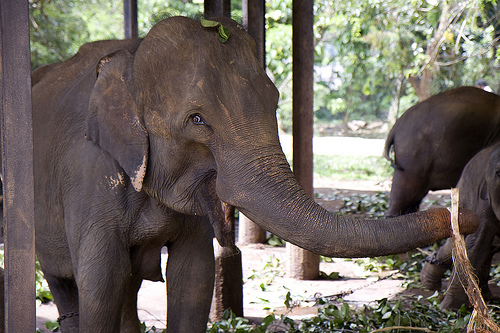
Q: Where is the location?
A: Zoo.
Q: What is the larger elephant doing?
A: Eating.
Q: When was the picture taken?
A: Daytime.